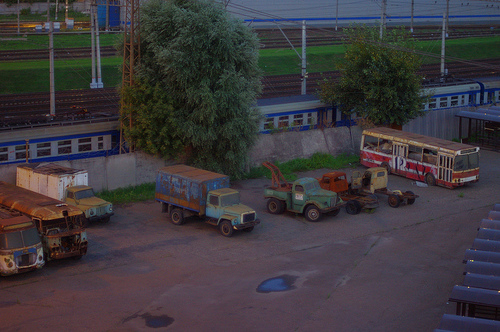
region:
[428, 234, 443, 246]
part of a parking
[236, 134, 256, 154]
part of a leaf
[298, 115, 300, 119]
part of a train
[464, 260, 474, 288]
part of a roof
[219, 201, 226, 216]
part of a truck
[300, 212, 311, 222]
part of a wheel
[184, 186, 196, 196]
side of a truck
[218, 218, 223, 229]
edge of a wheel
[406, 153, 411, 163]
part of a truck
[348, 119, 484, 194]
red and yellow bus in parking lot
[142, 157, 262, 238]
blue truck on parking lot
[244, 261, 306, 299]
small water puddle in parking lot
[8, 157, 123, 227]
white and yellow truck in parking lot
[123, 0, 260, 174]
large green tree bordering parking lot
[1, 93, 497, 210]
short concrete wall bordering parking lot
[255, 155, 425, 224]
three trucks parked next to each other in parking lot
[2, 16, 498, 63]
brown train tracks beyond concrete wall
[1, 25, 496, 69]
green grass bordering brown train tracks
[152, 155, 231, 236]
cargo carrying part of blue truck with brown rust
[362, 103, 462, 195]
old rusty vehicle in lot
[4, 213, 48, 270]
old rusty vehicle in lot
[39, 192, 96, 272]
old rusty vehicle in lot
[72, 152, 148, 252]
old rusty vehicle in lot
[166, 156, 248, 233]
old rusty vehicle in lot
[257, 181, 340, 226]
old rusty vehicle in lot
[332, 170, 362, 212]
old rusty vehicle in lot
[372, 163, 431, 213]
old rusty vehicle in lot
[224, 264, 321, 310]
small puddle in lot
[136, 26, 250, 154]
green tree by lot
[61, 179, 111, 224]
yellow front of an old box truck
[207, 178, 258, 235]
green front of an old box truck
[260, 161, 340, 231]
old green tow truck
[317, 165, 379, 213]
old red flat bed truck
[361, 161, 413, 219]
old tan flat bed truck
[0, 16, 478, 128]
rows of empty train tracks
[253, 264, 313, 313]
light reflected into a puddle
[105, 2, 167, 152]
a metal tower by a tree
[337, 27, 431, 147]
a tree growing by a cement fence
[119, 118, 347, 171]
a cement barrier wall in a parking lot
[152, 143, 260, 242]
rusty old box truck parked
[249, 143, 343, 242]
old tow truck parked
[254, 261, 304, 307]
shallow puddle in a parking lot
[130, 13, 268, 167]
big tree by a parking lot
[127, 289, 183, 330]
puddle drying in a parking lot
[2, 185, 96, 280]
two rusty old buses parked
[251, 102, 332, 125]
windows on a train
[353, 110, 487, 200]
red and white parked antique bus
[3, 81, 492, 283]
old rusty vehicles parked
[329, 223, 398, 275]
cracks in the parking lot's pavement